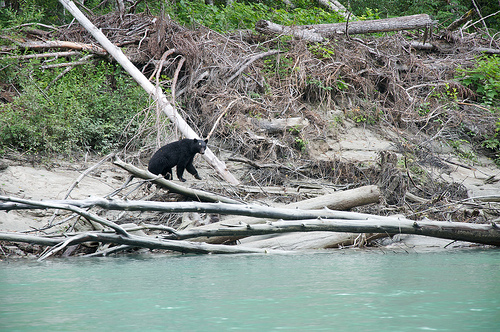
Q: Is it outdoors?
A: Yes, it is outdoors.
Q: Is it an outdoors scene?
A: Yes, it is outdoors.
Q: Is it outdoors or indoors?
A: It is outdoors.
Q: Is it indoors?
A: No, it is outdoors.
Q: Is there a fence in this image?
A: No, there are no fences.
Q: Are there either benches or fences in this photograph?
A: No, there are no fences or benches.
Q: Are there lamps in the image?
A: No, there are no lamps.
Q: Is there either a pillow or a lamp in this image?
A: No, there are no lamps or pillows.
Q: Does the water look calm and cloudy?
A: Yes, the water is calm and cloudy.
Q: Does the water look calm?
A: Yes, the water is calm.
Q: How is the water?
A: The water is calm.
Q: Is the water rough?
A: No, the water is calm.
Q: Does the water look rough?
A: No, the water is calm.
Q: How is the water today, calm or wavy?
A: The water is calm.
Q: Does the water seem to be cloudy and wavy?
A: No, the water is cloudy but calm.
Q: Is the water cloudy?
A: Yes, the water is cloudy.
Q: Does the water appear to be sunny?
A: No, the water is cloudy.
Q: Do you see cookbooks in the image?
A: No, there are no cookbooks.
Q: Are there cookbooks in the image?
A: No, there are no cookbooks.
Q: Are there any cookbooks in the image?
A: No, there are no cookbooks.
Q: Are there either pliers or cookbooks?
A: No, there are no cookbooks or pliers.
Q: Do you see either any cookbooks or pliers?
A: No, there are no cookbooks or pliers.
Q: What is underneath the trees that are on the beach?
A: The shrubs are underneath the trees.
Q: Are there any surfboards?
A: No, there are no surfboards.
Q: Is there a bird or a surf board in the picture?
A: No, there are no surfboards or birds.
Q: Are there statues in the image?
A: No, there are no statues.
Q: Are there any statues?
A: No, there are no statues.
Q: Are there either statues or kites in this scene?
A: No, there are no statues or kites.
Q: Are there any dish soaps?
A: No, there are no dish soaps.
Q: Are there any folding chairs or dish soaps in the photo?
A: No, there are no dish soaps or folding chairs.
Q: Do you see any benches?
A: No, there are no benches.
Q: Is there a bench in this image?
A: No, there are no benches.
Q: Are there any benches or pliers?
A: No, there are no benches or pliers.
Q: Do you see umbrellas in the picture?
A: No, there are no umbrellas.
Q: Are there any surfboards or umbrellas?
A: No, there are no umbrellas or surfboards.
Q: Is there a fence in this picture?
A: No, there are no fences.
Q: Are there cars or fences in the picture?
A: No, there are no fences or cars.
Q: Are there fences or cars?
A: No, there are no fences or cars.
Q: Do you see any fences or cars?
A: No, there are no fences or cars.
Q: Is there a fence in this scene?
A: No, there are no fences.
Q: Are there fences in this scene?
A: No, there are no fences.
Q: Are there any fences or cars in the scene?
A: No, there are no fences or cars.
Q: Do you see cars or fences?
A: No, there are no fences or cars.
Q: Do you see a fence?
A: No, there are no fences.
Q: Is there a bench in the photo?
A: No, there are no benches.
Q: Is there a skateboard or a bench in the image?
A: No, there are no benches or skateboards.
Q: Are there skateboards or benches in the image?
A: No, there are no benches or skateboards.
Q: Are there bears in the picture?
A: Yes, there is a bear.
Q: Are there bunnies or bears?
A: Yes, there is a bear.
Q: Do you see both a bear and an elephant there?
A: No, there is a bear but no elephants.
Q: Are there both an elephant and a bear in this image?
A: No, there is a bear but no elephants.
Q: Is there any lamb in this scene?
A: No, there are no lambs.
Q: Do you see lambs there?
A: No, there are no lambs.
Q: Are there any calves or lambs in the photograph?
A: No, there are no lambs or calves.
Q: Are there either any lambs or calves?
A: No, there are no lambs or calves.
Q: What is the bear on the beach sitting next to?
A: The bear is sitting next to the tree.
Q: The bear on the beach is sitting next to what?
A: The bear is sitting next to the tree.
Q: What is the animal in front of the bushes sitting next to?
A: The bear is sitting next to the tree.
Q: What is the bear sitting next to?
A: The bear is sitting next to the tree.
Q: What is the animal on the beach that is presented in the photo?
A: The animal is a bear.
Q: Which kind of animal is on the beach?
A: The animal is a bear.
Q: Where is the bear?
A: The bear is on the beach.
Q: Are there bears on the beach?
A: Yes, there is a bear on the beach.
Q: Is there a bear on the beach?
A: Yes, there is a bear on the beach.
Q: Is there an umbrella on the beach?
A: No, there is a bear on the beach.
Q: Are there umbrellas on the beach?
A: No, there is a bear on the beach.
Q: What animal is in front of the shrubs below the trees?
A: The bear is in front of the shrubs.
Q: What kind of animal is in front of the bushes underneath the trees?
A: The animal is a bear.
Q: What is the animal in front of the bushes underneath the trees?
A: The animal is a bear.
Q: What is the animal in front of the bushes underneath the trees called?
A: The animal is a bear.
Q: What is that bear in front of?
A: The bear is in front of the bushes.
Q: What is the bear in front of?
A: The bear is in front of the bushes.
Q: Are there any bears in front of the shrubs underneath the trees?
A: Yes, there is a bear in front of the bushes.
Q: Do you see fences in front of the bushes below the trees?
A: No, there is a bear in front of the shrubs.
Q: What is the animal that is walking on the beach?
A: The animal is a bear.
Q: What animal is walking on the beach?
A: The animal is a bear.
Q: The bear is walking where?
A: The bear is walking on the beach.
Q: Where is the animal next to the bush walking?
A: The bear is walking on the beach.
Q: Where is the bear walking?
A: The bear is walking on the beach.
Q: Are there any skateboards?
A: No, there are no skateboards.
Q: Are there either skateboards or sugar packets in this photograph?
A: No, there are no skateboards or sugar packets.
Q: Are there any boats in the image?
A: No, there are no boats.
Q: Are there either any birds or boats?
A: No, there are no boats or birds.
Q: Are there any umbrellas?
A: No, there are no umbrellas.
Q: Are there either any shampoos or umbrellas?
A: No, there are no umbrellas or shampoos.